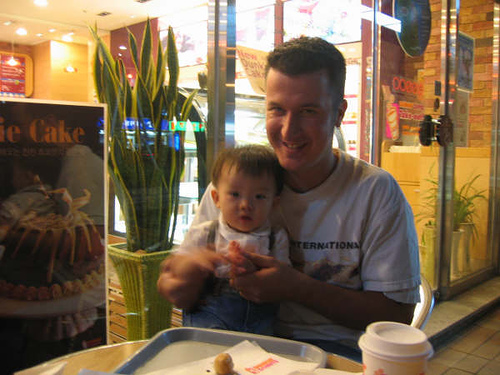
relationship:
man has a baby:
[159, 34, 421, 374] [168, 140, 296, 338]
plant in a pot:
[84, 27, 197, 340] [108, 243, 181, 340]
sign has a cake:
[2, 84, 110, 366] [6, 179, 110, 337]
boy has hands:
[168, 140, 296, 338] [191, 233, 255, 287]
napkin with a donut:
[203, 344, 318, 373] [212, 352, 237, 373]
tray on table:
[110, 317, 328, 371] [7, 328, 386, 372]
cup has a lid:
[361, 317, 432, 375] [353, 318, 438, 361]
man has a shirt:
[159, 34, 421, 374] [186, 145, 418, 354]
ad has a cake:
[2, 84, 110, 366] [6, 179, 110, 337]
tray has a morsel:
[110, 317, 328, 371] [212, 352, 237, 373]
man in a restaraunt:
[159, 34, 421, 374] [2, 1, 499, 373]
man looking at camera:
[156, 34, 420, 363] [207, 55, 368, 229]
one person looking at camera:
[168, 140, 296, 338] [207, 55, 368, 229]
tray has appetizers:
[110, 317, 328, 371] [212, 352, 237, 373]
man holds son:
[159, 34, 421, 374] [168, 140, 296, 338]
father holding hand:
[159, 34, 421, 374] [179, 234, 272, 300]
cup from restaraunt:
[361, 317, 432, 375] [2, 1, 499, 373]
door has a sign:
[371, 2, 494, 322] [383, 1, 486, 160]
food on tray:
[212, 352, 237, 373] [110, 317, 328, 371]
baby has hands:
[168, 140, 296, 338] [191, 233, 255, 287]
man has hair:
[159, 34, 421, 374] [261, 33, 352, 109]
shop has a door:
[2, 1, 499, 373] [371, 2, 494, 322]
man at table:
[159, 34, 421, 374] [7, 328, 386, 372]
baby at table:
[168, 140, 296, 338] [7, 328, 386, 372]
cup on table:
[361, 317, 432, 375] [7, 328, 386, 372]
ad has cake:
[2, 84, 110, 366] [6, 179, 110, 337]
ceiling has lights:
[1, 1, 384, 71] [1, 2, 499, 46]